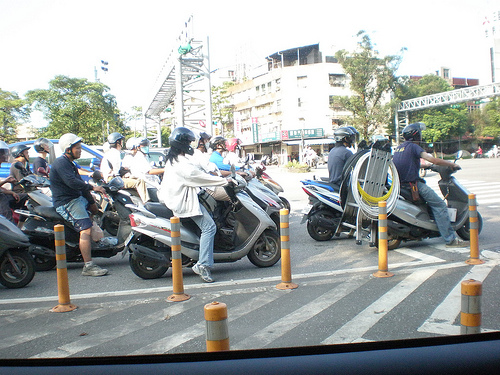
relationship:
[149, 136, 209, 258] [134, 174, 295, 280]
woman on motorcycle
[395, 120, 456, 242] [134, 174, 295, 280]
man on motorcycle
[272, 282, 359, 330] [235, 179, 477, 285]
line on street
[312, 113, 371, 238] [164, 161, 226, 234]
motorcyclist with jacket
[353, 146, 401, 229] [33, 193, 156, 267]
ladder on scooter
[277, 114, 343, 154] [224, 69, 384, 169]
sign on building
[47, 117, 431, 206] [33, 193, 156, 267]
people on scooter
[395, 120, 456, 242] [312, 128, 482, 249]
man on motorcycle